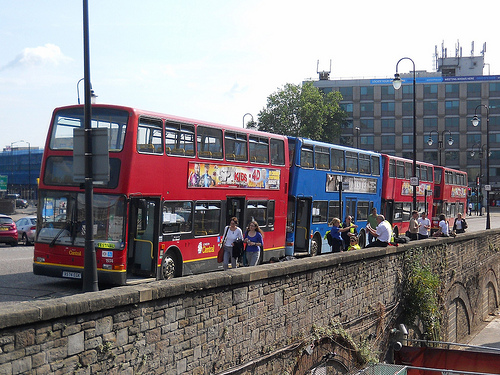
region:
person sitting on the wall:
[355, 211, 395, 256]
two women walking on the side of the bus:
[214, 215, 271, 268]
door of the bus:
[127, 194, 159, 281]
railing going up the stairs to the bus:
[132, 233, 155, 262]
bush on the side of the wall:
[397, 250, 447, 337]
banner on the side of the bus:
[185, 160, 283, 191]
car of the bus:
[286, 138, 382, 218]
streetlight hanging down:
[382, 52, 423, 162]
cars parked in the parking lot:
[2, 206, 34, 254]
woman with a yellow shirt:
[346, 234, 361, 255]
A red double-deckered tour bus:
[32, 100, 288, 273]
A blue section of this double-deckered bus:
[288, 138, 376, 253]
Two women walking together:
[221, 211, 271, 272]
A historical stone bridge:
[28, 276, 486, 346]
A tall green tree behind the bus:
[263, 80, 337, 134]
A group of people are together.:
[320, 203, 396, 252]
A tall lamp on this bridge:
[381, 37, 428, 245]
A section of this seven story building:
[463, 74, 498, 204]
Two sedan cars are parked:
[1, 209, 40, 249]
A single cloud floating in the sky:
[5, 28, 72, 96]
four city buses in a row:
[33, 103, 484, 281]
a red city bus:
[37, 100, 290, 267]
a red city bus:
[378, 151, 435, 241]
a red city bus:
[435, 164, 467, 217]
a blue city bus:
[286, 132, 381, 255]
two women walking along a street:
[217, 208, 266, 268]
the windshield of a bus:
[36, 189, 121, 249]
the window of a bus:
[139, 115, 161, 152]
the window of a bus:
[164, 120, 196, 157]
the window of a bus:
[248, 133, 271, 163]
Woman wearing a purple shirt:
[240, 216, 271, 267]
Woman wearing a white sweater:
[216, 213, 244, 271]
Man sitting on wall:
[365, 211, 394, 248]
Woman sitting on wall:
[432, 215, 454, 237]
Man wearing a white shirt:
[412, 208, 431, 243]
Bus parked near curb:
[36, 102, 294, 286]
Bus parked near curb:
[289, 123, 384, 253]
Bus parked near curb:
[378, 142, 438, 237]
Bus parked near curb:
[432, 158, 474, 225]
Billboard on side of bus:
[178, 156, 285, 199]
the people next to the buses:
[216, 207, 468, 269]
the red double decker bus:
[32, 102, 289, 285]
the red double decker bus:
[381, 152, 433, 239]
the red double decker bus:
[432, 164, 467, 227]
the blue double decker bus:
[287, 136, 383, 256]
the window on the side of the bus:
[162, 199, 192, 234]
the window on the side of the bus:
[135, 117, 164, 154]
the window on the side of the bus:
[165, 121, 195, 156]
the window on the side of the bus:
[300, 144, 313, 169]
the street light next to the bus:
[392, 57, 417, 214]